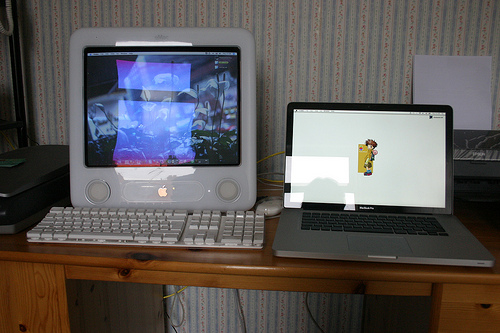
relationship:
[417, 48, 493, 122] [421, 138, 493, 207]
paper in printer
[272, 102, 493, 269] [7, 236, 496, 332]
laptop on top of desk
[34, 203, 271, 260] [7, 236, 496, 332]
keyboard on top of desk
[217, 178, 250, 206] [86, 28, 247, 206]
dial on monitor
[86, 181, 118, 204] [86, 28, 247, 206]
dial on monitor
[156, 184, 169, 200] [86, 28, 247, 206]
logo on monitor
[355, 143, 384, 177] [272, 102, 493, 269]
image on laptop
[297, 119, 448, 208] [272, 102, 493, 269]
screen of laptop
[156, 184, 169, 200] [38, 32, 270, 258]
logo on computer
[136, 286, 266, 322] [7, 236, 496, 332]
cords behind desk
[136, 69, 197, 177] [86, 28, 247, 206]
sunlight glaring on monitor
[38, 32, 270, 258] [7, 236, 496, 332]
computer on top of desk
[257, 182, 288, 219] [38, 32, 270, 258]
mouse next to computer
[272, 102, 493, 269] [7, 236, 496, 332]
laptop sitting on desk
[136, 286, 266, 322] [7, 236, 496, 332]
cords under desk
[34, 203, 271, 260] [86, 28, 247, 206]
keyboard in front of monitor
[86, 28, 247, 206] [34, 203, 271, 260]
monitor behind keyboard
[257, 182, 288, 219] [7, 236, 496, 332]
mouse on top of desk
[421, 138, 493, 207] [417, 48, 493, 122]
printer in paper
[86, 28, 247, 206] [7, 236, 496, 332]
monitor sitting on desk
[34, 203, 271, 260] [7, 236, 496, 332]
keyboard sitting on desk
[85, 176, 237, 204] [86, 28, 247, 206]
knobs on monitor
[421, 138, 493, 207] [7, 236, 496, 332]
printer in back of desk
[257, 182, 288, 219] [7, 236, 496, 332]
mouse sitting on desk